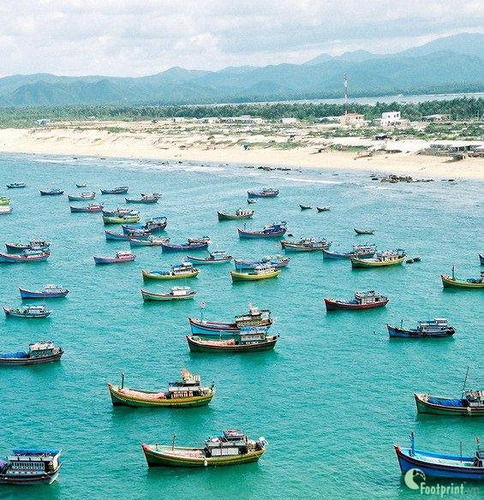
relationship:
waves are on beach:
[32, 152, 409, 195] [0, 94, 484, 181]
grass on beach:
[54, 116, 482, 162] [130, 120, 468, 169]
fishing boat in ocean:
[183, 325, 279, 352] [4, 153, 476, 499]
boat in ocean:
[323, 289, 389, 312] [4, 153, 476, 499]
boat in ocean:
[229, 258, 282, 281] [4, 153, 476, 499]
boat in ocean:
[140, 285, 196, 301] [4, 153, 476, 499]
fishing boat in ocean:
[385, 307, 455, 341] [4, 153, 476, 499]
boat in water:
[279, 234, 331, 257] [2, 152, 479, 495]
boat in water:
[226, 258, 280, 291] [2, 152, 479, 495]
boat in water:
[345, 246, 408, 267] [2, 152, 479, 495]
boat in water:
[323, 289, 389, 312] [2, 152, 479, 495]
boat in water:
[385, 317, 457, 338] [2, 152, 479, 495]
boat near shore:
[279, 234, 331, 257] [6, 105, 479, 180]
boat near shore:
[226, 258, 280, 291] [6, 105, 479, 180]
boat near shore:
[345, 246, 408, 267] [6, 105, 479, 180]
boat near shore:
[323, 289, 389, 312] [6, 105, 479, 180]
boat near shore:
[385, 317, 457, 338] [6, 105, 479, 180]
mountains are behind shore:
[0, 30, 481, 110] [10, 112, 477, 185]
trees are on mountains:
[2, 97, 481, 119] [10, 65, 481, 109]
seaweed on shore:
[25, 116, 481, 145] [6, 94, 482, 174]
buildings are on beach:
[338, 107, 364, 124] [4, 129, 483, 183]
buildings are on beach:
[373, 112, 402, 127] [4, 129, 483, 183]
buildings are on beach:
[219, 115, 263, 126] [4, 129, 483, 183]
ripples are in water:
[20, 145, 478, 498] [2, 152, 479, 495]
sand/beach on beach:
[1, 119, 477, 158] [13, 120, 478, 175]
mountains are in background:
[0, 30, 481, 110] [0, 4, 483, 104]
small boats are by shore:
[353, 225, 375, 238] [0, 127, 481, 193]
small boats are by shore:
[316, 203, 333, 214] [0, 127, 481, 193]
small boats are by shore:
[296, 202, 313, 213] [0, 127, 481, 193]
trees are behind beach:
[2, 97, 481, 119] [6, 118, 479, 181]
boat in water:
[244, 188, 284, 201] [167, 168, 217, 235]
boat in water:
[215, 208, 259, 223] [167, 168, 217, 235]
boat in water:
[126, 191, 164, 204] [167, 168, 217, 235]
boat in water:
[237, 219, 287, 236] [167, 168, 217, 235]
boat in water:
[160, 236, 210, 251] [167, 168, 217, 235]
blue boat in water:
[391, 429, 482, 492] [260, 354, 482, 493]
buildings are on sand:
[370, 107, 407, 133] [3, 125, 480, 183]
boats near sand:
[155, 168, 352, 257] [283, 139, 356, 179]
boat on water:
[318, 285, 389, 313] [2, 152, 479, 495]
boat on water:
[382, 316, 458, 344] [2, 152, 479, 495]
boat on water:
[345, 246, 409, 271] [2, 152, 479, 495]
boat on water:
[134, 280, 196, 304] [2, 152, 479, 495]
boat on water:
[234, 217, 287, 244] [2, 152, 479, 495]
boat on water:
[101, 366, 215, 410] [2, 152, 479, 495]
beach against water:
[6, 118, 479, 181] [182, 175, 350, 231]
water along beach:
[2, 152, 479, 495] [0, 113, 481, 177]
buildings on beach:
[241, 98, 467, 185] [153, 115, 483, 205]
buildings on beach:
[344, 104, 459, 134] [244, 143, 468, 175]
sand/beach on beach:
[1, 119, 477, 158] [0, 124, 483, 190]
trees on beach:
[2, 97, 481, 119] [184, 87, 480, 116]